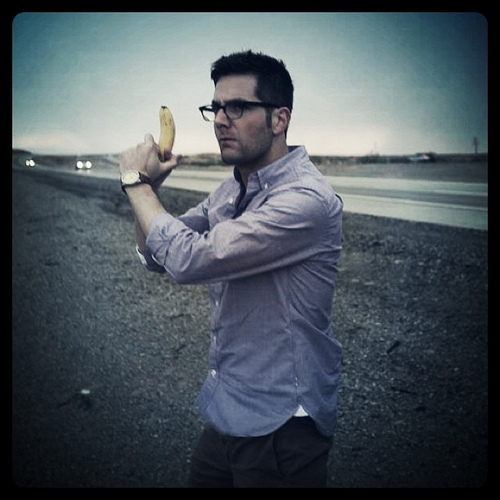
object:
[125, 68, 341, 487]
man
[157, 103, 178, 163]
banana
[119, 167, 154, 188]
wristwatch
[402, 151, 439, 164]
car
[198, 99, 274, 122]
glasses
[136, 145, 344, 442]
purple shirt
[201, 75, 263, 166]
facial expression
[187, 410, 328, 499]
pants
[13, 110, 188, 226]
distance